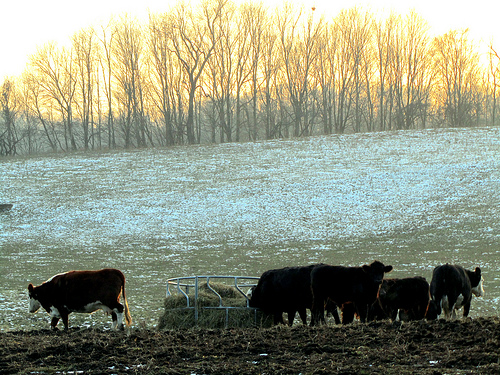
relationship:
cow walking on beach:
[29, 268, 132, 333] [24, 372, 204, 373]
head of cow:
[17, 271, 45, 317] [23, 265, 145, 344]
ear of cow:
[27, 281, 33, 289] [25, 268, 132, 334]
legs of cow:
[36, 314, 80, 337] [15, 260, 130, 337]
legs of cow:
[102, 303, 132, 333] [16, 243, 133, 352]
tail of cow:
[121, 272, 139, 326] [215, 238, 403, 345]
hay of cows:
[156, 281, 260, 329] [282, 262, 413, 319]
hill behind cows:
[5, 126, 498, 298] [7, 257, 497, 332]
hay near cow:
[156, 281, 260, 329] [430, 262, 487, 322]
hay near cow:
[164, 282, 254, 327] [24, 268, 133, 332]